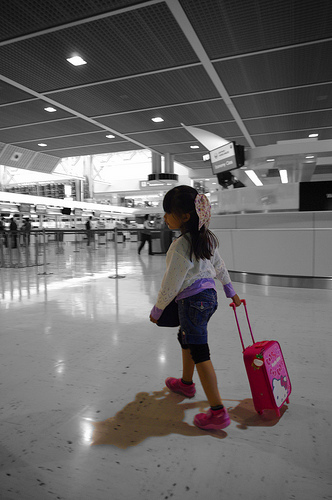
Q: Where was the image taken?
A: It was taken at the airport.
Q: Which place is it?
A: It is an airport.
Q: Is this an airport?
A: Yes, it is an airport.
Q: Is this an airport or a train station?
A: It is an airport.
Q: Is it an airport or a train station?
A: It is an airport.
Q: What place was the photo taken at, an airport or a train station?
A: It was taken at an airport.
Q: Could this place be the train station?
A: No, it is the airport.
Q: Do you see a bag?
A: Yes, there is a bag.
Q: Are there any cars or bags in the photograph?
A: Yes, there is a bag.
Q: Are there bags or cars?
A: Yes, there is a bag.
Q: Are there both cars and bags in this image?
A: No, there is a bag but no cars.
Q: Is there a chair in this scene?
A: No, there are no chairs.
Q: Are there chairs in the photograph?
A: No, there are no chairs.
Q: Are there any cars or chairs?
A: No, there are no chairs or cars.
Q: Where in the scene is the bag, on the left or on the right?
A: The bag is on the right of the image.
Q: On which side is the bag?
A: The bag is on the right of the image.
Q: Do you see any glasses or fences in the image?
A: No, there are no fences or glasses.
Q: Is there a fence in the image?
A: No, there are no fences.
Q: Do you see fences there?
A: No, there are no fences.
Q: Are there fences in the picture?
A: No, there are no fences.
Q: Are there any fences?
A: No, there are no fences.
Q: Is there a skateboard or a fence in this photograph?
A: No, there are no fences or skateboards.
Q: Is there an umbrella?
A: No, there are no umbrellas.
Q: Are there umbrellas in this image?
A: No, there are no umbrellas.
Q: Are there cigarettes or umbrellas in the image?
A: No, there are no umbrellas or cigarettes.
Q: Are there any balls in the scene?
A: No, there are no balls.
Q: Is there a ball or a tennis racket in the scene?
A: No, there are no balls or rackets.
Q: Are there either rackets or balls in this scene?
A: No, there are no balls or rackets.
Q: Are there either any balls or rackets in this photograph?
A: No, there are no balls or rackets.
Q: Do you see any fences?
A: No, there are no fences.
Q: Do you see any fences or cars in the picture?
A: No, there are no fences or cars.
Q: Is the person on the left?
A: Yes, the person is on the left of the image.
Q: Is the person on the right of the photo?
A: No, the person is on the left of the image.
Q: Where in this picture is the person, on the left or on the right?
A: The person is on the left of the image.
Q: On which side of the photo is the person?
A: The person is on the left of the image.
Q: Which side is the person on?
A: The person is on the left of the image.